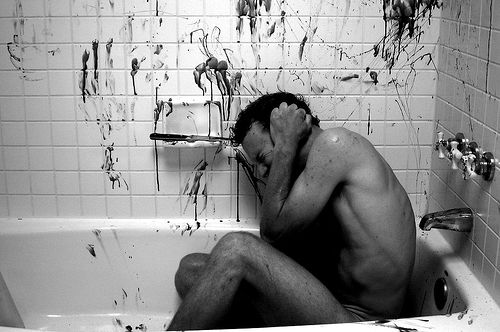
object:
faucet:
[464, 151, 497, 182]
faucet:
[419, 205, 476, 235]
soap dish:
[157, 97, 227, 155]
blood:
[77, 49, 94, 98]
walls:
[429, 0, 499, 304]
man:
[164, 90, 420, 331]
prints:
[79, 50, 91, 105]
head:
[227, 91, 321, 182]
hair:
[229, 91, 321, 149]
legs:
[164, 231, 351, 330]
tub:
[1, 216, 497, 332]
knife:
[145, 130, 227, 143]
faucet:
[435, 133, 462, 155]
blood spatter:
[78, 46, 92, 97]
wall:
[3, 2, 427, 218]